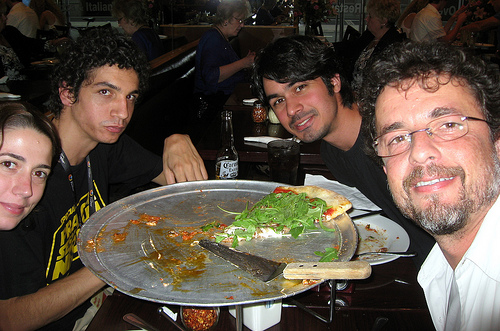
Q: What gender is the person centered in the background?
A: Female.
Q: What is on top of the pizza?
A: Spinach.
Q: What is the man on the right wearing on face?
A: Glasses.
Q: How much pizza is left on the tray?
A: One slice.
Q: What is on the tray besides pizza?
A: Spatula.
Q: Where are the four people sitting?
A: Table.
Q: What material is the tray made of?
A: Metal.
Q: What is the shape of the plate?
A: Round.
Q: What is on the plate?
A: Pizza.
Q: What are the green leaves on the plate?
A: Spinach.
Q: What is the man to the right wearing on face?
A: Glasses.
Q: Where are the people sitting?
A: Table.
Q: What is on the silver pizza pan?
A: A spatula and a slice of pizza.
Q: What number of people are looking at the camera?
A: Four.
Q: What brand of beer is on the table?
A: Corona.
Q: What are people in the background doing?
A: Eating.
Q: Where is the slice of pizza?
A: On the pizza pan.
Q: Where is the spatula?
A: On the pizza pan.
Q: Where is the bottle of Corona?
A: On the table.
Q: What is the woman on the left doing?
A: Looking at the camera.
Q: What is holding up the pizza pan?
A: A metal stand.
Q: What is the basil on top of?
A: Pizza.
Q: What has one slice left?
A: Pizza.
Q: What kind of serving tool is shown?
A: Pizza server.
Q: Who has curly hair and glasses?
A: A man.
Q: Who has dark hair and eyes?
A: A man.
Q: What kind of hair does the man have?
A: Curly.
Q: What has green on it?
A: Pizza.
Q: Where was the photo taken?
A: Restaurant.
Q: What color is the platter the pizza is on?
A: Silver.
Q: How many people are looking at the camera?
A: Four.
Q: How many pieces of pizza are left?
A: One.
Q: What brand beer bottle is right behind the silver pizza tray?
A: Corona.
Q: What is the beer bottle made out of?
A: Glass.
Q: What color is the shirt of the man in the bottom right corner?
A: White.